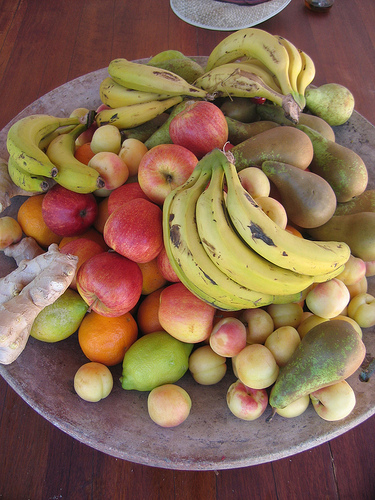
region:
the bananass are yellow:
[161, 218, 325, 295]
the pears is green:
[267, 332, 358, 407]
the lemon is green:
[122, 339, 199, 389]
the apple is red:
[85, 272, 148, 330]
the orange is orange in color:
[77, 321, 139, 362]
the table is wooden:
[22, 459, 139, 491]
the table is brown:
[45, 468, 194, 493]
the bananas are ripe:
[182, 191, 338, 275]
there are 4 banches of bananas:
[19, 33, 327, 274]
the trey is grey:
[87, 426, 283, 469]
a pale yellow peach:
[70, 361, 113, 404]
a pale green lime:
[116, 328, 195, 397]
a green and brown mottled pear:
[260, 318, 367, 427]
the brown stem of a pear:
[261, 405, 279, 425]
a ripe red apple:
[73, 247, 143, 317]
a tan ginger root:
[0, 240, 78, 366]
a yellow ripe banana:
[44, 116, 105, 195]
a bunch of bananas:
[6, 105, 107, 197]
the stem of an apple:
[85, 292, 101, 316]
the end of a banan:
[96, 173, 108, 189]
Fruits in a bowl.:
[7, 24, 373, 482]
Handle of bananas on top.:
[158, 141, 353, 318]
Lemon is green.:
[115, 328, 198, 400]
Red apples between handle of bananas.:
[26, 100, 223, 350]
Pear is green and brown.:
[262, 315, 368, 412]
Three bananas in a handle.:
[6, 102, 111, 203]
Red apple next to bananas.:
[97, 195, 178, 266]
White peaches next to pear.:
[233, 318, 299, 400]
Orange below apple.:
[72, 307, 142, 370]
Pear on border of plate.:
[298, 80, 361, 125]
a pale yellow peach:
[144, 381, 194, 429]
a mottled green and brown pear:
[262, 317, 369, 427]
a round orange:
[76, 306, 140, 366]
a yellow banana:
[44, 112, 106, 196]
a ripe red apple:
[102, 194, 165, 262]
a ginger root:
[0, 240, 81, 366]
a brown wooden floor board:
[40, 415, 101, 498]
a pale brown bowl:
[0, 53, 374, 471]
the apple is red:
[97, 185, 173, 280]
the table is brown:
[12, 410, 87, 496]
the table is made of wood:
[10, 392, 87, 492]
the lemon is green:
[105, 321, 211, 410]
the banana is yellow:
[156, 134, 350, 345]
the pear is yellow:
[231, 338, 286, 396]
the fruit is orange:
[83, 311, 152, 373]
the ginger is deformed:
[3, 243, 118, 425]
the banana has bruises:
[173, 153, 328, 333]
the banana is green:
[4, 114, 102, 241]